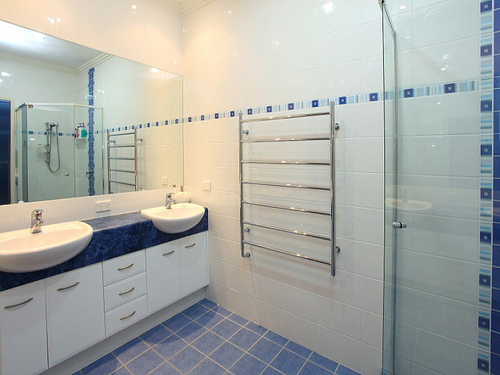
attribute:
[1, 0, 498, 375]
bathroom — blue, white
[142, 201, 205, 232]
sink — white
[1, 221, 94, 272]
sink — white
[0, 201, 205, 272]
sinks — oval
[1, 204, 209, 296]
counter — blue, stone, deep blue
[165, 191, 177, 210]
faucet — chrome, water tap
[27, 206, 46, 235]
faucet — chrome, water tap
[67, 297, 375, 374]
tile floor — blue, tiled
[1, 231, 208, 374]
cabinets — white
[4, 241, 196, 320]
handles — chrome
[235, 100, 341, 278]
towel rack — large, towel holder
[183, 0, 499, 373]
wall — tiled, white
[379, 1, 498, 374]
shower — enclosed, clear, glass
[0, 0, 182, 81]
wall — tiled, white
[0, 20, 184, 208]
mirror — it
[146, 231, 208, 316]
cabinet — white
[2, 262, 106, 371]
cabinet — white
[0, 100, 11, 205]
door — tiled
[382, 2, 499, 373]
walls — clear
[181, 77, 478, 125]
accent — dark, tile, light blue, blue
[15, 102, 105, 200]
shower — glass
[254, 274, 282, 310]
tile — white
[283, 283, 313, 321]
tile — white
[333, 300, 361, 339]
tile — white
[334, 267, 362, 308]
tile — white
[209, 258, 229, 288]
tile — white